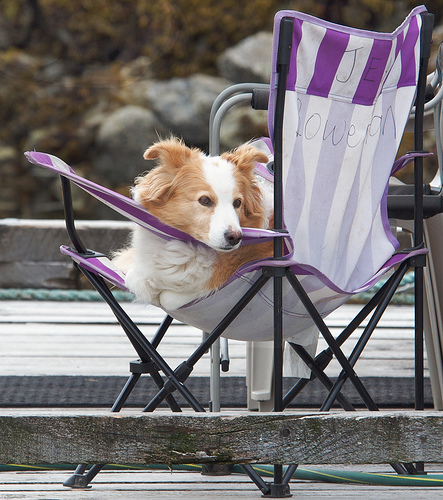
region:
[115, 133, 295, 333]
dog sitting on a chair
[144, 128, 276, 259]
head of a dog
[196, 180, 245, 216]
eyes of a dog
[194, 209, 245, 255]
mouth of a dog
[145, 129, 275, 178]
ears of a dog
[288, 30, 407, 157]
writings on back of chair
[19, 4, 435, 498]
a purple chair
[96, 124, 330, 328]
dog looking away at something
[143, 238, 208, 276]
fur of a dog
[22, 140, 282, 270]
arm rest of a chair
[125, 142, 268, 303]
dog laying down in chair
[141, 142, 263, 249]
brown and white head of dog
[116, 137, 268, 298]
brown and white dog in chair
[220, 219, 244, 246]
black and red nose of dog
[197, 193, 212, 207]
black large eye of dog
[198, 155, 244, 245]
white streak down face of dog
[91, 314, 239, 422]
metal black poles of chair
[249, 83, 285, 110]
black arm rest on chair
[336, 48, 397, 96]
sharpie on back of chair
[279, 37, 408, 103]
purple and white stripes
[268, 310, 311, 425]
There is a black post from this chair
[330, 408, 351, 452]
There is wood that is visible here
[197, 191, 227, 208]
This dog has very warm, brown eyes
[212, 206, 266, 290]
This dog has a very bright white snout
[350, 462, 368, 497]
There is a green and yellow hose visible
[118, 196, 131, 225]
There is a purple arm to the chair here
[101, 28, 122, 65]
There are brown trees that are in the background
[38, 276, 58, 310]
There is some green rope that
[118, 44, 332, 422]
Jackson Mingus took this photo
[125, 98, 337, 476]
This photo has a great precision to it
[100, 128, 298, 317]
dog is sitting in chair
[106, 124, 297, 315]
dog is brown and white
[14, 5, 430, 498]
chair is foldable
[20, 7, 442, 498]
chair is purple and white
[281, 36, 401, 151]
name on back of chair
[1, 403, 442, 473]
wood railing behind chair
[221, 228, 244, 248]
dogs nose is brown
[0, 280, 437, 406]
wood deck is front of chair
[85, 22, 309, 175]
pile of large rocks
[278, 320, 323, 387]
white tag under chair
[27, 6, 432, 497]
purple and white folding chair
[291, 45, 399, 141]
name written on fabric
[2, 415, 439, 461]
worn wood surface of board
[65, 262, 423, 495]
black legs of chair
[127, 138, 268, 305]
front of reclined dog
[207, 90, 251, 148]
curved gray metal pole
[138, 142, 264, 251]
tan and white fur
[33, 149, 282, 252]
head resting on arm of chair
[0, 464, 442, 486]
yellow and green hose